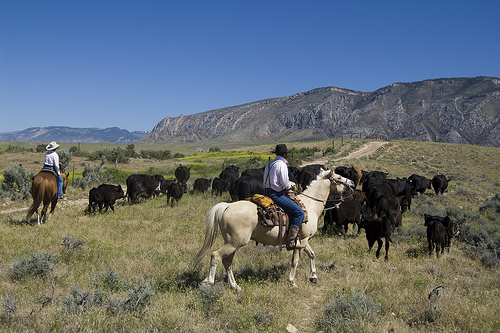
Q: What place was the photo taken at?
A: It was taken at the field.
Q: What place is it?
A: It is a field.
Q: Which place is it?
A: It is a field.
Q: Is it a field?
A: Yes, it is a field.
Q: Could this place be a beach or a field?
A: It is a field.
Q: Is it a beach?
A: No, it is a field.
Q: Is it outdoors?
A: Yes, it is outdoors.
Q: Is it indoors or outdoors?
A: It is outdoors.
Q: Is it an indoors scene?
A: No, it is outdoors.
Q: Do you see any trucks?
A: No, there are no trucks.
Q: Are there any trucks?
A: No, there are no trucks.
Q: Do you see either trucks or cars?
A: No, there are no trucks or cars.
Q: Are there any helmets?
A: No, there are no helmets.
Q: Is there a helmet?
A: No, there are no helmets.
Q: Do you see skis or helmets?
A: No, there are no helmets or skis.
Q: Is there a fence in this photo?
A: No, there are no fences.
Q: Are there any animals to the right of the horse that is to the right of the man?
A: Yes, there are animals to the right of the horse.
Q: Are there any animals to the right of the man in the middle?
A: Yes, there are animals to the right of the man.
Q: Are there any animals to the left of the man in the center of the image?
A: No, the animals are to the right of the man.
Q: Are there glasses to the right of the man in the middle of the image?
A: No, there are animals to the right of the man.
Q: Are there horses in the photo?
A: Yes, there is a horse.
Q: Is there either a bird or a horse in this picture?
A: Yes, there is a horse.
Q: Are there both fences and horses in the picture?
A: No, there is a horse but no fences.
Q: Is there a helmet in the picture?
A: No, there are no helmets.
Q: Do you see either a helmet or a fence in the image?
A: No, there are no helmets or fences.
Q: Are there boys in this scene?
A: No, there are no boys.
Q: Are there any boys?
A: No, there are no boys.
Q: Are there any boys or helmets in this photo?
A: No, there are no boys or helmets.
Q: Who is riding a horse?
A: The man is riding a horse.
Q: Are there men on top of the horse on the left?
A: Yes, there is a man on top of the horse.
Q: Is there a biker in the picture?
A: No, there are no bikers.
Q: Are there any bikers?
A: No, there are no bikers.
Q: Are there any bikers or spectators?
A: No, there are no bikers or spectators.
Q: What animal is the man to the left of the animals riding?
A: The man is riding a horse.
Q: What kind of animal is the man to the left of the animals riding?
A: The man is riding a horse.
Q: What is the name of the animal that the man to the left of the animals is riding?
A: The animal is a horse.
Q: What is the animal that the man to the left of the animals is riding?
A: The animal is a horse.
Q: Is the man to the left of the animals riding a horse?
A: Yes, the man is riding a horse.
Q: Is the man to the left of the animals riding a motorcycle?
A: No, the man is riding a horse.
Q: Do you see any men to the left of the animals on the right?
A: Yes, there is a man to the left of the animals.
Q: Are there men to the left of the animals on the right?
A: Yes, there is a man to the left of the animals.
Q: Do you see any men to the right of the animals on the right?
A: No, the man is to the left of the animals.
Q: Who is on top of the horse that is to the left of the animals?
A: The man is on top of the horse.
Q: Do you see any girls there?
A: No, there are no girls.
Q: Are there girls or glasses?
A: No, there are no girls or glasses.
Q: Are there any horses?
A: Yes, there is a horse.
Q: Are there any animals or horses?
A: Yes, there is a horse.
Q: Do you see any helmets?
A: No, there are no helmets.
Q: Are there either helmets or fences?
A: No, there are no helmets or fences.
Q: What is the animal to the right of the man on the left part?
A: The animal is a horse.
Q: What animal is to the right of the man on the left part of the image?
A: The animal is a horse.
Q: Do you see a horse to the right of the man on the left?
A: Yes, there is a horse to the right of the man.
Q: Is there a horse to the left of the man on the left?
A: No, the horse is to the right of the man.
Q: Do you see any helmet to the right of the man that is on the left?
A: No, there is a horse to the right of the man.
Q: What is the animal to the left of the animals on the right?
A: The animal is a horse.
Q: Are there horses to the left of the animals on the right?
A: Yes, there is a horse to the left of the animals.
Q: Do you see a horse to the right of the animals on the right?
A: No, the horse is to the left of the animals.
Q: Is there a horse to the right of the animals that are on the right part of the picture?
A: No, the horse is to the left of the animals.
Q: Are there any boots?
A: Yes, there are boots.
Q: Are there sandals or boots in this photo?
A: Yes, there are boots.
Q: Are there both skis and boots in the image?
A: No, there are boots but no skis.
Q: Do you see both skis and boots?
A: No, there are boots but no skis.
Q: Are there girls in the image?
A: No, there are no girls.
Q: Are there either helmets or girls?
A: No, there are no girls or helmets.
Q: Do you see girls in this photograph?
A: No, there are no girls.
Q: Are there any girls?
A: No, there are no girls.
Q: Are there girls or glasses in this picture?
A: No, there are no girls or glasses.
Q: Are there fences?
A: No, there are no fences.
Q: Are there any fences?
A: No, there are no fences.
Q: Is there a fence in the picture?
A: No, there are no fences.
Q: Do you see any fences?
A: No, there are no fences.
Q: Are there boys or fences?
A: No, there are no fences or boys.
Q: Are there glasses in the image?
A: No, there are no glasses.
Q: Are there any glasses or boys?
A: No, there are no glasses or boys.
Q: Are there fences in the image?
A: No, there are no fences.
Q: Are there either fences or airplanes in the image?
A: No, there are no fences or airplanes.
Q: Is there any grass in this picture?
A: Yes, there is grass.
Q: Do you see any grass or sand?
A: Yes, there is grass.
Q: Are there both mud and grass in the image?
A: No, there is grass but no mud.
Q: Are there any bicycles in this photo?
A: No, there are no bicycles.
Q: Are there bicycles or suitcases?
A: No, there are no bicycles or suitcases.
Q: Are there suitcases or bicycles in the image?
A: No, there are no bicycles or suitcases.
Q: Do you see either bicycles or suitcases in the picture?
A: No, there are no bicycles or suitcases.